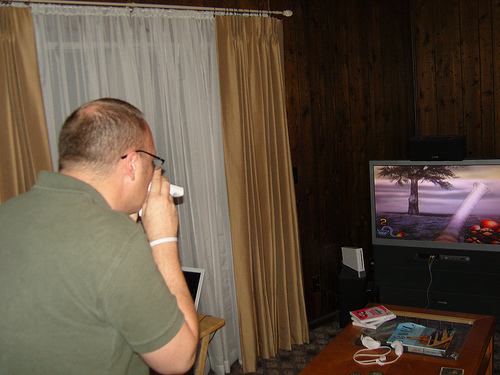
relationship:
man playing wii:
[2, 99, 201, 375] [337, 244, 368, 282]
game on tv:
[337, 244, 368, 282] [369, 160, 497, 253]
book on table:
[350, 303, 397, 322] [299, 301, 496, 375]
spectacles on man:
[153, 158, 165, 170] [2, 99, 201, 375]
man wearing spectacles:
[2, 99, 201, 375] [153, 155, 165, 171]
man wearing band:
[2, 99, 201, 375] [146, 237, 183, 248]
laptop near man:
[181, 262, 208, 315] [2, 99, 201, 375]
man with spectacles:
[2, 99, 201, 375] [153, 158, 165, 170]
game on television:
[337, 244, 368, 282] [369, 160, 497, 253]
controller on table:
[353, 335, 406, 368] [299, 301, 496, 375]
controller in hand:
[353, 335, 406, 368] [140, 168, 182, 238]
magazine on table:
[388, 319, 459, 357] [299, 301, 496, 375]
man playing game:
[2, 99, 201, 375] [337, 244, 368, 282]